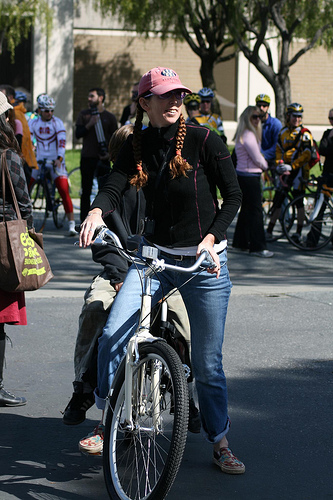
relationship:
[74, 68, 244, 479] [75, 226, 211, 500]
person on a bicycle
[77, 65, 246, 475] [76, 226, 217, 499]
person sitting on a bicycle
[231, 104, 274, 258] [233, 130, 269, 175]
people wearing sweater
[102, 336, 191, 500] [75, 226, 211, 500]
wheel on bicycle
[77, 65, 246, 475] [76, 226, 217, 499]
person riding a bicycle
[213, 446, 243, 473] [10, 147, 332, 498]
left foot on ground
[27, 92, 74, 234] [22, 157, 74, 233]
man riding a bike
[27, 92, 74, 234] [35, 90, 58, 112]
man wearing a helmet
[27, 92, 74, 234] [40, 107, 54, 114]
man wearing sunglasses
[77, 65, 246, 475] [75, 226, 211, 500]
person sitting on a bicycle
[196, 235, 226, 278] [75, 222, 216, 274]
hand on handlebar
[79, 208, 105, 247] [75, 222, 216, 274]
hand on handlebar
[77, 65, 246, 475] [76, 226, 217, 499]
person on a bicycle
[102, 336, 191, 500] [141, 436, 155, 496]
wheel has a spoke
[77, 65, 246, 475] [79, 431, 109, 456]
person wearing a shoe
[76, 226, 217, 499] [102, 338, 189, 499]
bicycle has a tire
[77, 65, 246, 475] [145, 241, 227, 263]
person wearing a belt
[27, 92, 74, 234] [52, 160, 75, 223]
man has a leg